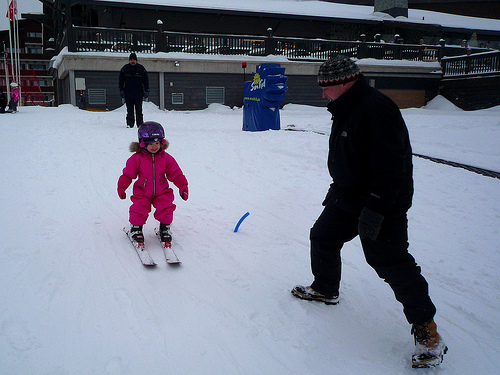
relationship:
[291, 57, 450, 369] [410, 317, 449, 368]
man wearing boot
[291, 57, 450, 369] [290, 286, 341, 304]
man wearing boot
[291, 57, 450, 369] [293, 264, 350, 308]
man wearing shoe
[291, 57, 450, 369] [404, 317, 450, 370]
man wearing shoe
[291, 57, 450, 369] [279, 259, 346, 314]
man wearing boot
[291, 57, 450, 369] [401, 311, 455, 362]
man wearing boot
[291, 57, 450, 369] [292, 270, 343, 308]
man wearing boot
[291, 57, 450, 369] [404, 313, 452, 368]
man wearing boot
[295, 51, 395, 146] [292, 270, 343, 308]
man wearing boot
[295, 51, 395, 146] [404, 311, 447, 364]
man wearing boot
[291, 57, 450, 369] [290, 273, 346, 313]
man wearing boot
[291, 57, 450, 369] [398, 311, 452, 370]
man wearing boot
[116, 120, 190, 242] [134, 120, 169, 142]
child wearing a helmet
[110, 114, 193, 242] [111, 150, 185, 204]
child in clothing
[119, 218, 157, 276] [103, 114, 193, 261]
ski in child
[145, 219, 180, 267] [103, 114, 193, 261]
ski in child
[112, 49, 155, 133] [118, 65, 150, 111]
man in clothing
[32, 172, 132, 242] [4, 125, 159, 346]
ground covered in snow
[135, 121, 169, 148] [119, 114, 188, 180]
helmet on child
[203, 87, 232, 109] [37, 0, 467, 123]
window on side of building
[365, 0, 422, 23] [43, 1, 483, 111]
chimney on house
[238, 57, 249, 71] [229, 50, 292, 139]
light on machinery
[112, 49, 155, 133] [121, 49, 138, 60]
man wearing cap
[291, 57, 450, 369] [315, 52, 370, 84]
man wearing cap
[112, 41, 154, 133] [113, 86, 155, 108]
man wearing gloves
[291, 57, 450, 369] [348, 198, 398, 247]
man wearing gloves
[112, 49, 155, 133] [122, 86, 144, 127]
man wearing pants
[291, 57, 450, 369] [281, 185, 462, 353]
man wearing pants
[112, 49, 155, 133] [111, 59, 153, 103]
man wearing jacket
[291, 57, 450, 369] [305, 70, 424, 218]
man wearing jacket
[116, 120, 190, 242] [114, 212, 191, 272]
child wearing skiis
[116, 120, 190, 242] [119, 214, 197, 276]
child wearing helmet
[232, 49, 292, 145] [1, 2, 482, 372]
sign for skate park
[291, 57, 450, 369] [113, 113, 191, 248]
man watching child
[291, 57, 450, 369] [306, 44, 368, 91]
man wears beanie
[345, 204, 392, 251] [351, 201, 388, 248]
gloves on hand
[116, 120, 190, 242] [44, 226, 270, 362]
child skiing on snow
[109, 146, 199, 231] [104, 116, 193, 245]
snow suit on girl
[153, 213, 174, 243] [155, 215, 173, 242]
shoe strapped in to ski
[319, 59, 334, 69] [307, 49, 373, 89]
dot on hat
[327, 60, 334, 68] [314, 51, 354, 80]
dot on hat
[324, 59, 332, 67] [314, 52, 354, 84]
dot on hat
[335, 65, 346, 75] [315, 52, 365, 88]
dot on cap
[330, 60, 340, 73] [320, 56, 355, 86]
dot on hat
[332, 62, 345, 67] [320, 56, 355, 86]
dot on hat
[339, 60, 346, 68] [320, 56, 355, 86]
dot on hat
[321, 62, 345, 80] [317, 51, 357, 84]
dots on hat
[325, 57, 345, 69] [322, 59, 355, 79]
dots on hat